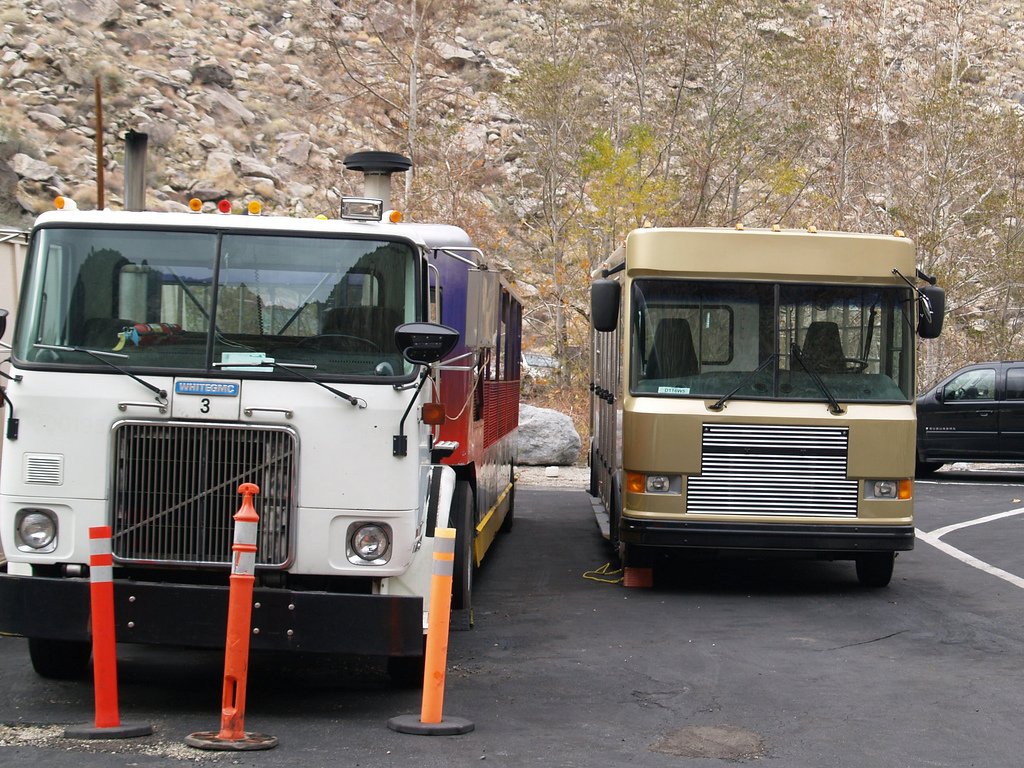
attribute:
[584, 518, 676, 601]
front tire — Blocked 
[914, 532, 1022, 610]
line — white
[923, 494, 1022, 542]
line — white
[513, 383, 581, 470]
large rock — large 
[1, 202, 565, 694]
white truck — white 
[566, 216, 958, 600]
bus — gold, black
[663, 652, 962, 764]
road — dark grey